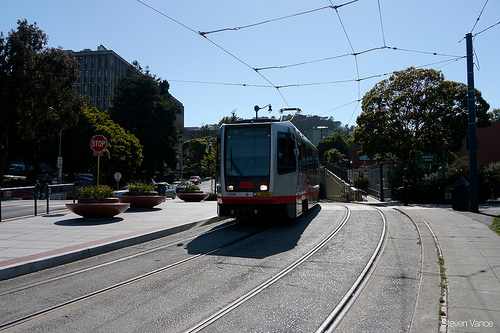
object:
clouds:
[170, 37, 237, 74]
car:
[216, 119, 319, 221]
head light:
[259, 184, 268, 191]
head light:
[227, 185, 234, 192]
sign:
[90, 135, 107, 155]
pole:
[97, 154, 100, 186]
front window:
[227, 121, 270, 176]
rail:
[0, 224, 360, 333]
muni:
[212, 118, 322, 223]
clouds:
[199, 100, 220, 110]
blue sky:
[0, 0, 499, 122]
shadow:
[184, 203, 323, 260]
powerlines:
[143, 0, 490, 117]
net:
[131, 0, 499, 121]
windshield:
[222, 125, 276, 191]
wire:
[139, 1, 494, 118]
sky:
[0, 0, 499, 127]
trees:
[0, 18, 186, 191]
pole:
[462, 33, 478, 206]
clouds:
[287, 87, 336, 103]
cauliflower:
[346, 66, 491, 205]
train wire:
[253, 53, 354, 73]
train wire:
[204, 3, 334, 36]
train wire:
[275, 79, 357, 89]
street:
[0, 176, 499, 333]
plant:
[72, 183, 114, 201]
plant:
[127, 179, 154, 193]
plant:
[184, 184, 200, 191]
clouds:
[84, 8, 128, 43]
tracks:
[0, 200, 386, 333]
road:
[315, 220, 477, 323]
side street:
[0, 176, 218, 271]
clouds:
[60, 9, 116, 47]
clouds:
[294, 38, 337, 59]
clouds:
[360, 22, 416, 47]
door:
[270, 124, 298, 196]